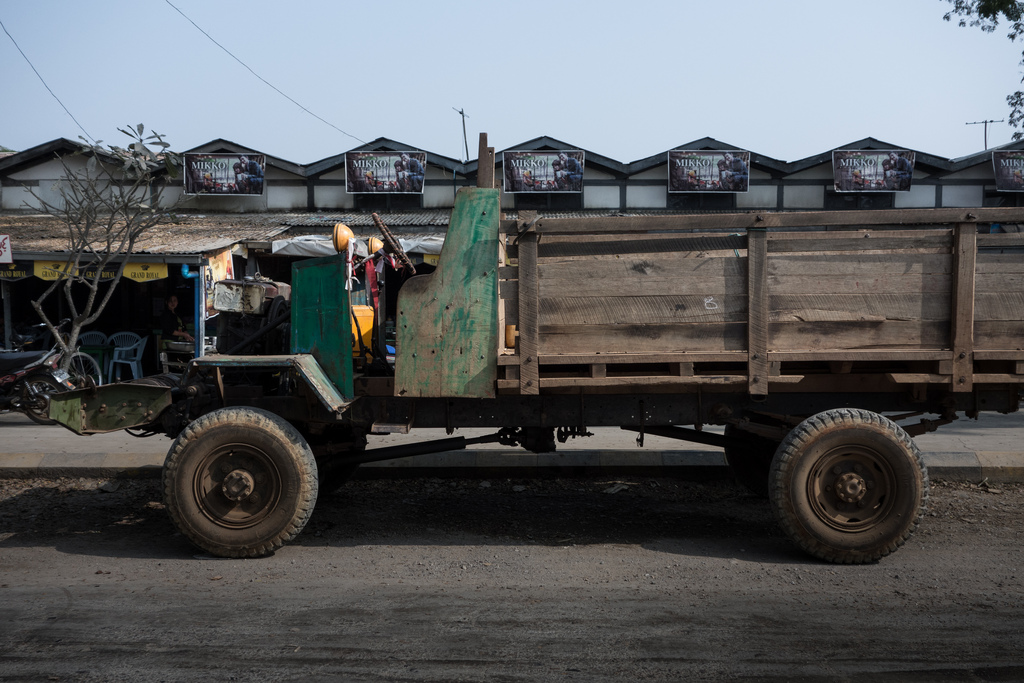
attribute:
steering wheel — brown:
[362, 202, 420, 283]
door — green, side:
[383, 175, 518, 410]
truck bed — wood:
[500, 209, 1020, 393]